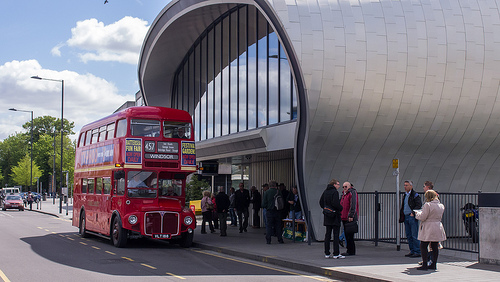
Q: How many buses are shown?
A: One.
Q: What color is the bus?
A: Red.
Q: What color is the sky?
A: Blue.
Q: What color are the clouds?
A: White.